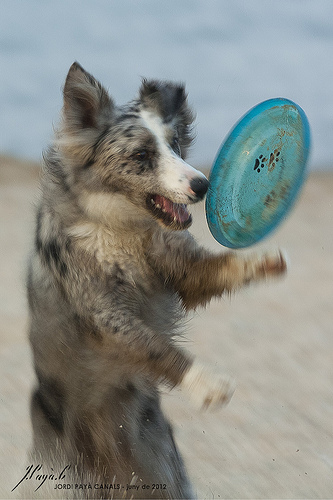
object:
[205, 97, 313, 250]
frisbee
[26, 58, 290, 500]
dog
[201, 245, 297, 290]
paw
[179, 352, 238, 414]
paw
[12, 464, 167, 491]
copyright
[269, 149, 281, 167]
paw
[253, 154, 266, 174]
paw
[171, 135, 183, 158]
eye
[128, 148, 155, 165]
eye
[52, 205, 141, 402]
fur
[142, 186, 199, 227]
mouth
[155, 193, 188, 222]
tongue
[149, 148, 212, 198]
nose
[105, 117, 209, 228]
face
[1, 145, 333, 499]
beach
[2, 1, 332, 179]
water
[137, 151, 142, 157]
pupil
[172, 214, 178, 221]
tooth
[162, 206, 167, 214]
tooth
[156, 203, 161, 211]
tooth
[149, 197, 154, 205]
tooth